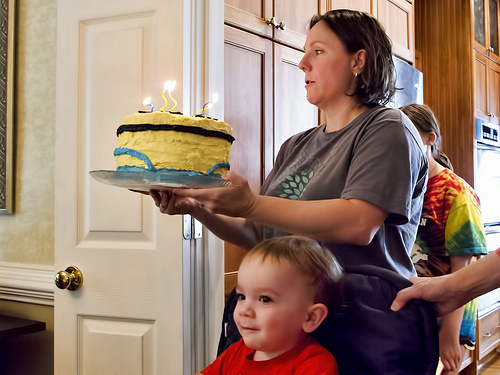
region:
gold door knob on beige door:
[50, 261, 85, 292]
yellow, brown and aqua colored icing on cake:
[113, 100, 230, 176]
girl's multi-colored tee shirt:
[415, 170, 490, 271]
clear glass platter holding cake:
[80, 164, 235, 196]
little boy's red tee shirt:
[190, 338, 341, 371]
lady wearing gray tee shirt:
[251, 103, 416, 279]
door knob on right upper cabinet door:
[263, 10, 278, 26]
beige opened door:
[53, 3, 195, 371]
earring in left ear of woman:
[342, 66, 363, 82]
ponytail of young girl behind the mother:
[429, 139, 456, 173]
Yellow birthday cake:
[88, 78, 245, 203]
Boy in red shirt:
[184, 229, 349, 371]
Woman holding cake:
[99, 7, 437, 372]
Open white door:
[45, 0, 215, 372]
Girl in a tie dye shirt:
[386, 100, 474, 374]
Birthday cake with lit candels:
[73, 73, 249, 208]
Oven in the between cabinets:
[471, 111, 498, 233]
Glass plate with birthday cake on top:
[84, 162, 236, 201]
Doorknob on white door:
[53, 263, 86, 295]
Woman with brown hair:
[112, 3, 453, 364]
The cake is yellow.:
[110, 78, 240, 200]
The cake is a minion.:
[107, 79, 260, 200]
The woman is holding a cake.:
[113, 22, 425, 258]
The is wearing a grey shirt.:
[258, 30, 393, 268]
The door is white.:
[55, 29, 190, 356]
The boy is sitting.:
[221, 237, 349, 369]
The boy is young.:
[234, 254, 346, 374]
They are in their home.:
[14, 9, 498, 372]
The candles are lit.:
[103, 66, 231, 131]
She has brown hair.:
[284, 9, 399, 155]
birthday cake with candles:
[65, 78, 248, 205]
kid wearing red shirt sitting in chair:
[109, 239, 359, 374]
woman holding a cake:
[61, 20, 483, 250]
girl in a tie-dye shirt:
[400, 98, 490, 355]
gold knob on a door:
[36, 247, 87, 310]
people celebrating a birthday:
[86, 47, 493, 350]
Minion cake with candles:
[67, 80, 279, 227]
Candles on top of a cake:
[106, 77, 223, 142]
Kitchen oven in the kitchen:
[461, 112, 498, 251]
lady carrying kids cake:
[78, 5, 433, 239]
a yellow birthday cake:
[88, 71, 241, 188]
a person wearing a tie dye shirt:
[425, 165, 499, 247]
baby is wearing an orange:
[193, 340, 369, 373]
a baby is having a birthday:
[193, 223, 343, 372]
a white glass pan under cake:
[91, 169, 226, 192]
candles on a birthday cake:
[118, 71, 223, 119]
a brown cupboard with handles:
[223, 0, 312, 161]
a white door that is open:
[49, 202, 198, 373]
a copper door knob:
[53, 244, 88, 302]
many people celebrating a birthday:
[98, 7, 499, 372]